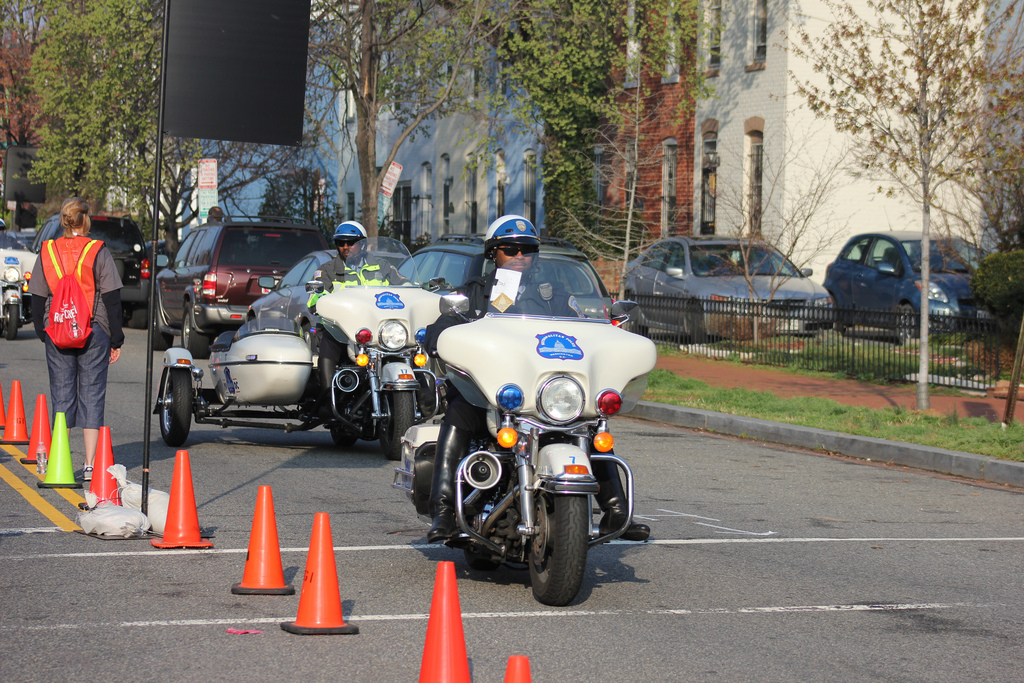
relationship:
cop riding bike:
[421, 210, 653, 550] [389, 310, 651, 609]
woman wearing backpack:
[53, 197, 138, 435] [41, 273, 96, 352]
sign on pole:
[156, 72, 306, 131] [135, 132, 181, 508]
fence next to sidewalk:
[699, 286, 833, 390] [735, 342, 816, 414]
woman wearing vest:
[25, 196, 129, 483] [31, 227, 99, 333]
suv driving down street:
[118, 186, 278, 349] [651, 467, 865, 627]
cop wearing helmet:
[421, 210, 653, 550] [496, 202, 516, 272]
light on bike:
[468, 368, 527, 444] [405, 288, 708, 634]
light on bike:
[589, 394, 618, 423] [472, 323, 617, 572]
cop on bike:
[392, 184, 552, 362] [389, 310, 651, 609]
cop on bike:
[304, 217, 428, 430] [389, 310, 651, 609]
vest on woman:
[25, 208, 119, 329] [25, 206, 192, 496]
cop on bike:
[442, 234, 551, 312] [389, 310, 651, 609]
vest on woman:
[27, 235, 126, 336] [25, 196, 129, 483]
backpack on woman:
[42, 258, 142, 367] [25, 196, 129, 483]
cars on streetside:
[227, 190, 716, 342] [175, 157, 789, 372]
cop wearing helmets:
[421, 210, 653, 550] [309, 204, 595, 269]